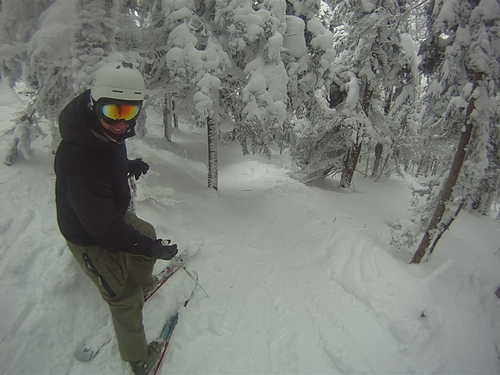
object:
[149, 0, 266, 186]
tree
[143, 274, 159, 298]
foot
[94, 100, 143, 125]
goggles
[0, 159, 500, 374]
ground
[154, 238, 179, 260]
hand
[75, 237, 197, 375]
skis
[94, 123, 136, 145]
hood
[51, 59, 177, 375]
man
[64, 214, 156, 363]
pants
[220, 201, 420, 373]
tracks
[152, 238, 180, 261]
gloved right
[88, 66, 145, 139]
hard hat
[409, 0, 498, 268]
tree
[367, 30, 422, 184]
tree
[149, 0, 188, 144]
tree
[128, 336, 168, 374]
boot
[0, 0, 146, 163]
trees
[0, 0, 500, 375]
snow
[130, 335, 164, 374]
foot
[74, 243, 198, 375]
ski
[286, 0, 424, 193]
tree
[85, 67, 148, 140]
head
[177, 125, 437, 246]
trail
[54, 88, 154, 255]
black coat